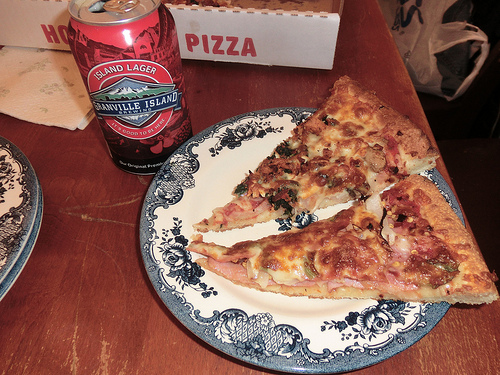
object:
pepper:
[301, 252, 319, 279]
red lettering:
[240, 33, 261, 61]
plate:
[0, 134, 48, 308]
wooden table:
[0, 0, 500, 375]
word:
[38, 22, 61, 46]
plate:
[133, 104, 473, 375]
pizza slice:
[175, 171, 500, 309]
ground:
[469, 140, 499, 222]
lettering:
[150, 65, 157, 75]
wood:
[358, 35, 382, 77]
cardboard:
[1, 0, 346, 72]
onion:
[407, 251, 464, 290]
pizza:
[190, 72, 445, 236]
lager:
[65, 0, 196, 178]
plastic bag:
[381, 0, 494, 106]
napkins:
[0, 52, 99, 133]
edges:
[135, 105, 484, 374]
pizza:
[177, 25, 264, 63]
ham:
[246, 178, 269, 199]